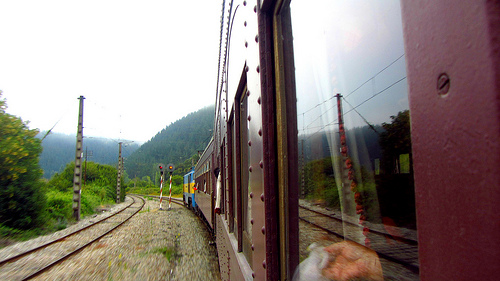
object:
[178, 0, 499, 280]
train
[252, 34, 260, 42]
rivets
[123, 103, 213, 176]
forest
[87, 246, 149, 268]
gravel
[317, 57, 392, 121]
reflection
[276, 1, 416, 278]
glass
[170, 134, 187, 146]
trees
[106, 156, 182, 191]
hills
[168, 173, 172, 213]
pole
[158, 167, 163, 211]
pole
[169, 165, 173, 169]
light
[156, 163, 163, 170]
light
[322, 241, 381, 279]
hand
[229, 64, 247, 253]
window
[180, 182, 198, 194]
stripe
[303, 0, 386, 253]
curtain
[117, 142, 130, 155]
power lines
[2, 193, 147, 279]
track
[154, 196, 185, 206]
tracks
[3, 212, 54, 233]
grass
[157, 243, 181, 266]
grass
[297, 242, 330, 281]
item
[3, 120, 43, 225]
bushes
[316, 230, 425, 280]
passenger